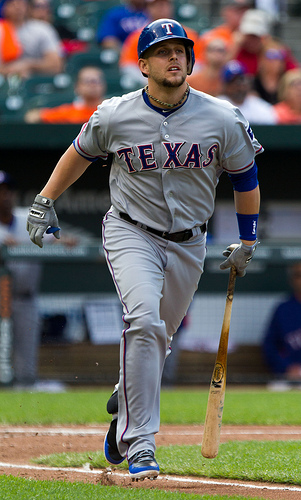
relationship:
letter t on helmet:
[156, 20, 175, 33] [134, 23, 198, 61]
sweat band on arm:
[234, 209, 260, 241] [219, 97, 261, 270]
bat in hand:
[195, 240, 259, 464] [216, 230, 262, 280]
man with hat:
[28, 19, 262, 477] [136, 18, 195, 66]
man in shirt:
[27, 66, 103, 120] [39, 103, 95, 121]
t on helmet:
[160, 20, 172, 35] [142, 20, 174, 35]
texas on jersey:
[112, 131, 218, 180] [79, 87, 263, 237]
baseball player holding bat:
[61, 12, 269, 449] [201, 260, 237, 491]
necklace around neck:
[143, 84, 189, 106] [146, 77, 187, 108]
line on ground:
[1, 453, 100, 485] [176, 429, 249, 491]